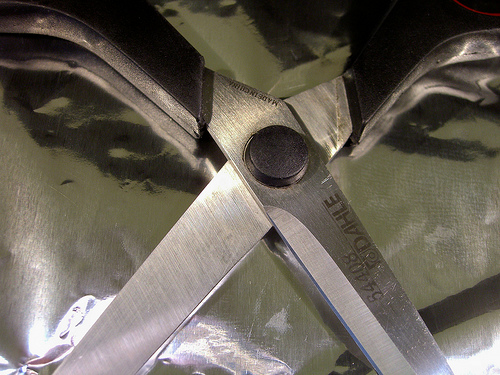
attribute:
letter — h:
[337, 209, 355, 229]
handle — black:
[2, 2, 213, 128]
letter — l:
[327, 202, 354, 217]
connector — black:
[248, 122, 311, 189]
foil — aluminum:
[0, 114, 158, 296]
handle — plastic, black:
[1, 5, 498, 144]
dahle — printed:
[322, 191, 394, 267]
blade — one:
[57, 140, 447, 373]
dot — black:
[238, 120, 316, 194]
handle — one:
[12, 4, 494, 158]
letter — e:
[322, 190, 341, 208]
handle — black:
[1, 2, 253, 160]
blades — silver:
[48, 157, 461, 374]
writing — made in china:
[318, 191, 388, 306]